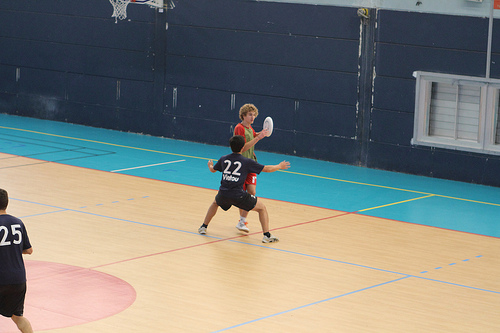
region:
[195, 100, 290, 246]
two Frisbee players indoors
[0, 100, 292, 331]
three Frisbee players indoors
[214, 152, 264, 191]
navy shirt with numbers on it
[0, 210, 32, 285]
navy shirt with numbers on it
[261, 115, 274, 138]
white Frisbee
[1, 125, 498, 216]
yellow line on wooden floor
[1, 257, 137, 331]
red cicrcle on wooden floor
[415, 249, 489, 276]
dotted blue line on wooden floor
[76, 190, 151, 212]
dotted blue line on wooden floor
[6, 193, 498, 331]
solid blue lines on wooden floor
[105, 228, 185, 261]
pink line on basketball court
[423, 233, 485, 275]
broken blue lines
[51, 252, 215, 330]
large pink circle on court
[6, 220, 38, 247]
large numbers on black jersey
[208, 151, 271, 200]
medium black jersey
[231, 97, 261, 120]
man's head with bushy blond hair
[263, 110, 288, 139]
white Frisbee in man's hand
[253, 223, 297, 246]
man wearing black socks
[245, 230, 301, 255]
white sneakers with blue trim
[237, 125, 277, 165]
red and gray short sleeve shirt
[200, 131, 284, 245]
a boy playing defense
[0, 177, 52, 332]
a boy wearing a number 25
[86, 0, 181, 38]
a basket ball hoop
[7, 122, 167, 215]
painted line on the court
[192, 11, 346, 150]
a blue painted wall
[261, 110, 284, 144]
a white Frisbee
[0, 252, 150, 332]
a painted shape on the floor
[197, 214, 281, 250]
the kid's gym shoes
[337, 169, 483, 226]
neon blue paint on the floor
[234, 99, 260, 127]
a boy with curly blonde hair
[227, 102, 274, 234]
man with frisbee standing on a basketball court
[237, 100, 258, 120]
man with light curly hair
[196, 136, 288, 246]
man in black shirt has arms outstretched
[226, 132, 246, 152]
man in black shirt has dark hair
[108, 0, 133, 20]
basketball net above court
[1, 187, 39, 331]
man wearing black shorts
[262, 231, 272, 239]
man wearing black socks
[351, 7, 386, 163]
paint on wall is peeling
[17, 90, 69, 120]
scuff marks on wall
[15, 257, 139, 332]
center circle on floor is red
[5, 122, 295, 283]
Three players are seen.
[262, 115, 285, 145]
Ball is white color.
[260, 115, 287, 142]
One ball is seen.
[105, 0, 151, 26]
Net is white color.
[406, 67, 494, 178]
Window is white color.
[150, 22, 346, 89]
Wall is grey color.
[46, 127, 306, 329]
Lines are drawn in the floor.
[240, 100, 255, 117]
hair is brown color.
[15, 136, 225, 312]
Ground is blue, brown and red color.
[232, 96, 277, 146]
Boy is holding the ball.